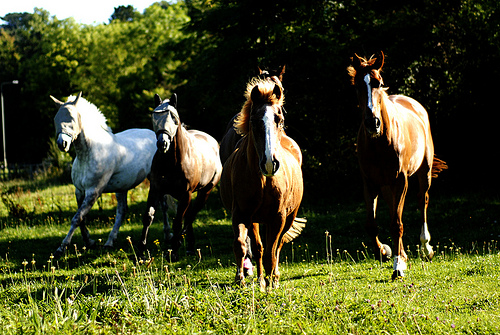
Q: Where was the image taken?
A: It was taken at the field.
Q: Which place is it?
A: It is a field.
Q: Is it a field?
A: Yes, it is a field.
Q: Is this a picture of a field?
A: Yes, it is showing a field.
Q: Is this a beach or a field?
A: It is a field.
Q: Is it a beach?
A: No, it is a field.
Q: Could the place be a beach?
A: No, it is a field.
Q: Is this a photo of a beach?
A: No, the picture is showing a field.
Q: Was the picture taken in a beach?
A: No, the picture was taken in a field.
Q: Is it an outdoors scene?
A: Yes, it is outdoors.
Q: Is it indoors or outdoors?
A: It is outdoors.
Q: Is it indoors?
A: No, it is outdoors.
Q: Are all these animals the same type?
A: Yes, all the animals are horses.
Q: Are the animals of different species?
A: No, all the animals are horses.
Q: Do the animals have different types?
A: No, all the animals are horses.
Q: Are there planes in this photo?
A: No, there are no planes.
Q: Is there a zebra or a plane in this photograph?
A: No, there are no airplanes or zebras.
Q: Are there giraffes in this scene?
A: No, there are no giraffes.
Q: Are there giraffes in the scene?
A: No, there are no giraffes.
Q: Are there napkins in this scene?
A: No, there are no napkins.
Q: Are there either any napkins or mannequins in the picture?
A: No, there are no napkins or mannequins.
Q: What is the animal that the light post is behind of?
A: The animal is a horse.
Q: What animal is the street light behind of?
A: The light post is behind the horse.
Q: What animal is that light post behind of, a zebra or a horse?
A: The light post is behind a horse.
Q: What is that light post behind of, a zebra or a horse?
A: The light post is behind a horse.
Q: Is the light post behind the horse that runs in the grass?
A: Yes, the light post is behind the horse.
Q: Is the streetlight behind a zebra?
A: No, the streetlight is behind the horse.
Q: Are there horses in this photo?
A: Yes, there is a horse.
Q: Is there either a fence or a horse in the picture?
A: Yes, there is a horse.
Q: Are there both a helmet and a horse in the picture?
A: No, there is a horse but no helmets.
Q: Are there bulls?
A: No, there are no bulls.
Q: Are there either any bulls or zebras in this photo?
A: No, there are no bulls or zebras.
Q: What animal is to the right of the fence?
A: The animal is a horse.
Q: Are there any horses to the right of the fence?
A: Yes, there is a horse to the right of the fence.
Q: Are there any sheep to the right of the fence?
A: No, there is a horse to the right of the fence.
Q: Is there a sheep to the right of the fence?
A: No, there is a horse to the right of the fence.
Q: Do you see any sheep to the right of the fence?
A: No, there is a horse to the right of the fence.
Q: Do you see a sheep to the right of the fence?
A: No, there is a horse to the right of the fence.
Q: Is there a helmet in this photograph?
A: No, there are no helmets.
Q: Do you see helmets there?
A: No, there are no helmets.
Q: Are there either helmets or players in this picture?
A: No, there are no helmets or players.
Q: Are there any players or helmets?
A: No, there are no helmets or players.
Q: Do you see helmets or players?
A: No, there are no helmets or players.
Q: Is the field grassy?
A: Yes, the field is grassy.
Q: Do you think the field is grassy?
A: Yes, the field is grassy.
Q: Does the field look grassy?
A: Yes, the field is grassy.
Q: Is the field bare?
A: No, the field is grassy.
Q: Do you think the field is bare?
A: No, the field is grassy.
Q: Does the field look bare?
A: No, the field is grassy.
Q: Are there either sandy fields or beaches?
A: No, there is a field but it is grassy.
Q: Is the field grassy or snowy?
A: The field is grassy.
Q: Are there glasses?
A: No, there are no glasses.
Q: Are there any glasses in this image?
A: No, there are no glasses.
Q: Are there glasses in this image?
A: No, there are no glasses.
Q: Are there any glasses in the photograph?
A: No, there are no glasses.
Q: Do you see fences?
A: Yes, there is a fence.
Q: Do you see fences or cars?
A: Yes, there is a fence.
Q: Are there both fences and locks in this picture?
A: No, there is a fence but no locks.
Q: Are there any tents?
A: No, there are no tents.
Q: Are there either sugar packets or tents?
A: No, there are no tents or sugar packets.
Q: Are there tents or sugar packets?
A: No, there are no tents or sugar packets.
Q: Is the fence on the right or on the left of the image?
A: The fence is on the left of the image.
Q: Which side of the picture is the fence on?
A: The fence is on the left of the image.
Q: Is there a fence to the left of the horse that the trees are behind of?
A: Yes, there is a fence to the left of the horse.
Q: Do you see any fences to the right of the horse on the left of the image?
A: No, the fence is to the left of the horse.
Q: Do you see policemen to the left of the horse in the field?
A: No, there is a fence to the left of the horse.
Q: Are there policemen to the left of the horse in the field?
A: No, there is a fence to the left of the horse.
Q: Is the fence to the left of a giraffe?
A: No, the fence is to the left of the horse.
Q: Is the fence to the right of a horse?
A: No, the fence is to the left of a horse.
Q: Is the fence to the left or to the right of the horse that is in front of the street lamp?
A: The fence is to the left of the horse.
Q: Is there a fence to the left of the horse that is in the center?
A: Yes, there is a fence to the left of the horse.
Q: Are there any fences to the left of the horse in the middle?
A: Yes, there is a fence to the left of the horse.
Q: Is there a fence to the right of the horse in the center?
A: No, the fence is to the left of the horse.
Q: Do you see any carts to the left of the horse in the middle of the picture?
A: No, there is a fence to the left of the horse.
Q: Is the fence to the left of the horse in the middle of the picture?
A: Yes, the fence is to the left of the horse.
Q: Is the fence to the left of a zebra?
A: No, the fence is to the left of the horse.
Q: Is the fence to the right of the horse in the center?
A: No, the fence is to the left of the horse.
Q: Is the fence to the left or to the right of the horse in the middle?
A: The fence is to the left of the horse.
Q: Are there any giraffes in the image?
A: No, there are no giraffes.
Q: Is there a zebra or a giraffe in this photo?
A: No, there are no giraffes or zebras.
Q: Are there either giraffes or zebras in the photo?
A: No, there are no giraffes or zebras.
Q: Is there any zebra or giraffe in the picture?
A: No, there are no zebras or giraffes.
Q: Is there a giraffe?
A: No, there are no giraffes.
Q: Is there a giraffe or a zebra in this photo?
A: No, there are no giraffes or zebras.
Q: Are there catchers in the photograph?
A: No, there are no catchers.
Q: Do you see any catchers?
A: No, there are no catchers.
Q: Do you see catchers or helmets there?
A: No, there are no catchers or helmets.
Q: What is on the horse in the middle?
A: The mask is on the horse.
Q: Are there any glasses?
A: No, there are no glasses.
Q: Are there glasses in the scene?
A: No, there are no glasses.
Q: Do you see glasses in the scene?
A: No, there are no glasses.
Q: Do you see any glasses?
A: No, there are no glasses.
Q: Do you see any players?
A: No, there are no players.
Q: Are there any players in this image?
A: No, there are no players.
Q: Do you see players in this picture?
A: No, there are no players.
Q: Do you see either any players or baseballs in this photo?
A: No, there are no players or baseballs.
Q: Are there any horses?
A: Yes, there is a horse.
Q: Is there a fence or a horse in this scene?
A: Yes, there is a horse.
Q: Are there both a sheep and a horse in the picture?
A: No, there is a horse but no sheep.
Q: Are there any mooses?
A: No, there are no mooses.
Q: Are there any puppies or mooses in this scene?
A: No, there are no mooses or puppies.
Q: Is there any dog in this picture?
A: No, there are no dogs.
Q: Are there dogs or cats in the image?
A: No, there are no dogs or cats.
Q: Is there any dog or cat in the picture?
A: No, there are no dogs or cats.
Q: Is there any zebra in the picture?
A: No, there are no zebras.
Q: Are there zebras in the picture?
A: No, there are no zebras.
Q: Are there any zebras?
A: No, there are no zebras.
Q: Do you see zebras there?
A: No, there are no zebras.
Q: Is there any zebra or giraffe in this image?
A: No, there are no zebras or giraffes.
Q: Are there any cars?
A: No, there are no cars.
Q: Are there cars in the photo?
A: No, there are no cars.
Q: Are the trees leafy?
A: Yes, the trees are leafy.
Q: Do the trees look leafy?
A: Yes, the trees are leafy.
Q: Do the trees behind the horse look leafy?
A: Yes, the trees are leafy.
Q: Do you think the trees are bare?
A: No, the trees are leafy.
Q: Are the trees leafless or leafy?
A: The trees are leafy.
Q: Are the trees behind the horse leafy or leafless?
A: The trees are leafy.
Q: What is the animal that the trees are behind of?
A: The animal is a horse.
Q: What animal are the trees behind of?
A: The trees are behind the horse.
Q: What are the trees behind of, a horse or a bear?
A: The trees are behind a horse.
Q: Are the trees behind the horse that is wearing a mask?
A: Yes, the trees are behind the horse.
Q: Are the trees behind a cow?
A: No, the trees are behind the horse.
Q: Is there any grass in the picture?
A: Yes, there is grass.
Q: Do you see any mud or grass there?
A: Yes, there is grass.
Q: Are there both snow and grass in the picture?
A: No, there is grass but no snow.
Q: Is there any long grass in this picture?
A: Yes, there is long grass.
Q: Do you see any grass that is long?
A: Yes, there is grass that is long.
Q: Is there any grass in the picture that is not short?
A: Yes, there is long grass.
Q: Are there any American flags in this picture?
A: No, there are no American flags.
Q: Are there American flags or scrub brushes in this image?
A: No, there are no American flags or scrub brushes.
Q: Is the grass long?
A: Yes, the grass is long.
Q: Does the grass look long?
A: Yes, the grass is long.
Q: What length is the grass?
A: The grass is long.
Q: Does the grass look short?
A: No, the grass is long.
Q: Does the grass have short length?
A: No, the grass is long.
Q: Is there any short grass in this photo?
A: No, there is grass but it is long.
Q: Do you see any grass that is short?
A: No, there is grass but it is long.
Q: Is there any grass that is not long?
A: No, there is grass but it is long.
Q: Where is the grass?
A: The grass is in the field.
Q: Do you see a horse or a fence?
A: Yes, there is a horse.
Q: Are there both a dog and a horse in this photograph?
A: No, there is a horse but no dogs.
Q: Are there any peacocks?
A: No, there are no peacocks.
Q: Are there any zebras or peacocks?
A: No, there are no peacocks or zebras.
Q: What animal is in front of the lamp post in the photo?
A: The horse is in front of the lamp post.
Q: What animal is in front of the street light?
A: The horse is in front of the lamp post.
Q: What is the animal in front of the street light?
A: The animal is a horse.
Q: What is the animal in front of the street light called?
A: The animal is a horse.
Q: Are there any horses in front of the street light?
A: Yes, there is a horse in front of the street light.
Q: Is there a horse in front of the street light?
A: Yes, there is a horse in front of the street light.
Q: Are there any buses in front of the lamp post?
A: No, there is a horse in front of the lamp post.